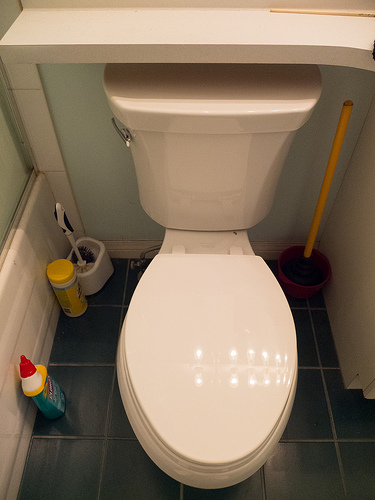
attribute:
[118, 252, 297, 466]
toilet lid — white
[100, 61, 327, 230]
toilet tank — white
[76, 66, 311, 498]
toilet — white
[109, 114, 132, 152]
toilet flusher — chrome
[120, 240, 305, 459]
seat — white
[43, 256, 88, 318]
cleaner — chemical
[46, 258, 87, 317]
bottle — yellow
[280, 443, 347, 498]
tile — blue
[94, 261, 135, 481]
white groutline — small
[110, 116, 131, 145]
toilet handle — flushing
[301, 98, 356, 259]
handle — yellow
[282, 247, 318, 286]
plunger — yellow, black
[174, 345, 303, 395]
lights — reflecting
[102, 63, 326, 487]
toilet — flushing, white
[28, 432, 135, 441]
grout line — small, white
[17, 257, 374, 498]
floor — white, small